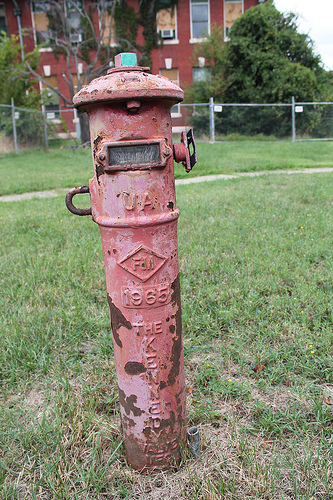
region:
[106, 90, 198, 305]
this is a hydrant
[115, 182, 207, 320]
the hydrant is metallic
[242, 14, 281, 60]
this is a tree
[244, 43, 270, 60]
the leaves are green in color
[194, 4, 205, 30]
this is a window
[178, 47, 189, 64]
this is the wall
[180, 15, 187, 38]
the wall is red in color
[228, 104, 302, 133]
this is a fence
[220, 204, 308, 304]
this is a grass area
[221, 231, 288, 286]
the grass is green in color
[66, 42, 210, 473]
Rusty fire hydrant standing on grass.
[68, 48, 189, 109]
Top of red rusty fire hydrant.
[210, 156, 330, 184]
Sidewalk running through middle of grass lawn.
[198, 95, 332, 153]
Fence behind fire hydrant next to building.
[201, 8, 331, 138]
Trees growing on other side of fence next to building.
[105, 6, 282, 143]
Red building behind fence.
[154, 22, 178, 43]
Air condition unit in a window on building.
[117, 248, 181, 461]
Writing engraved on rusy fire hydrant.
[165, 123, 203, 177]
Knob on side of fire hydrant.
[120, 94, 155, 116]
Screw beneath top of fire hydrant.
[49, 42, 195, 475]
small red pole in the grass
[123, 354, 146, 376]
rust on the pole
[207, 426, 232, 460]
patch of brown grass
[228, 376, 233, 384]
little yellow flower in the grass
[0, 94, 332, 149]
chain link fence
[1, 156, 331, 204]
narrow sidewalk running through the grass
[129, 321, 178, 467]
writing on the pole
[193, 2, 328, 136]
wide dark green tree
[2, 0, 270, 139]
red brick building behind the fence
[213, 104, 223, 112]
white sign on the fence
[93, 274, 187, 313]
the year 1965 is printed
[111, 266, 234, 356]
the year 1965 is printed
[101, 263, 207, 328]
the year 1965 is printed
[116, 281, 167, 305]
the year 1965 is printed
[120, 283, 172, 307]
Date stamped into an old fireplug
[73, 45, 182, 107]
Cap of an old-fashioned fireplug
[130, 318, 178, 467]
Name of the manufacturer who made this fireplug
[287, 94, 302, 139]
Vertical support post for a chain-link fence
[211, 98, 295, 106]
Horizontal support post for a chain-link fence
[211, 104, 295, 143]
Chain-link security fence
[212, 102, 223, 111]
Sign on a chain-link security fence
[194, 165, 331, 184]
Concrete sidewalk winding through the grass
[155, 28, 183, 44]
In window air conditioner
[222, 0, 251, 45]
Boarded up window in building